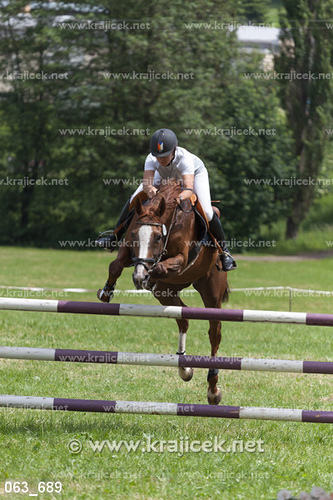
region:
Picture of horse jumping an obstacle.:
[19, 125, 318, 469]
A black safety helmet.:
[143, 125, 182, 166]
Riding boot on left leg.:
[203, 208, 239, 275]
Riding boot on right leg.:
[98, 195, 132, 251]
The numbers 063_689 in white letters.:
[0, 475, 68, 497]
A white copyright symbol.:
[64, 430, 86, 459]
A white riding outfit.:
[138, 150, 213, 216]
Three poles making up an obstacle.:
[22, 293, 289, 429]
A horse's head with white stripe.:
[122, 191, 167, 292]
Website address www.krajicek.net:
[85, 433, 269, 459]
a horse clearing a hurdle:
[92, 174, 242, 404]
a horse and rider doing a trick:
[95, 125, 241, 408]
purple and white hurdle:
[0, 292, 330, 421]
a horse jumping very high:
[95, 176, 236, 407]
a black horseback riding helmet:
[149, 125, 177, 160]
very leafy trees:
[0, 20, 332, 261]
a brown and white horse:
[97, 173, 239, 408]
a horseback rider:
[96, 124, 237, 274]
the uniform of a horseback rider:
[91, 147, 235, 278]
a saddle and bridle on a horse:
[115, 181, 217, 289]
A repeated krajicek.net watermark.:
[57, 435, 266, 454]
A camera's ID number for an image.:
[2, 478, 64, 497]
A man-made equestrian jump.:
[7, 330, 319, 426]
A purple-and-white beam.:
[21, 390, 176, 429]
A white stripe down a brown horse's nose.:
[139, 224, 148, 270]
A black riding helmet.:
[150, 127, 180, 158]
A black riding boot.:
[214, 215, 233, 265]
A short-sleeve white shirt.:
[177, 150, 206, 184]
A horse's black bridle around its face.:
[125, 251, 164, 264]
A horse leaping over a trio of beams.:
[97, 125, 240, 378]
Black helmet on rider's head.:
[126, 107, 224, 188]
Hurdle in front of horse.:
[1, 297, 317, 438]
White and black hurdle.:
[13, 345, 316, 374]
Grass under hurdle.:
[29, 421, 250, 487]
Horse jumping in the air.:
[77, 119, 276, 336]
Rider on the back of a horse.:
[126, 112, 236, 280]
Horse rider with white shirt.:
[138, 141, 216, 206]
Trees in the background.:
[14, 127, 174, 252]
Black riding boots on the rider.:
[195, 209, 229, 287]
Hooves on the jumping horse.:
[170, 343, 255, 420]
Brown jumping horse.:
[95, 177, 283, 381]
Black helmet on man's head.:
[116, 99, 209, 163]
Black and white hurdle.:
[4, 295, 330, 427]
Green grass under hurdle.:
[52, 431, 150, 485]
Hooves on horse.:
[149, 329, 244, 433]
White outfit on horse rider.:
[147, 139, 221, 217]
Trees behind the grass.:
[32, 181, 77, 249]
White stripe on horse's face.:
[128, 215, 167, 294]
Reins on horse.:
[116, 186, 201, 274]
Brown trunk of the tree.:
[269, 105, 323, 219]